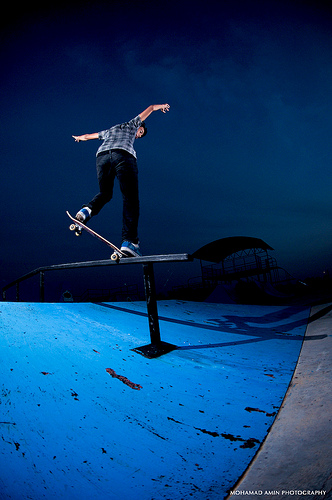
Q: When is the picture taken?
A: Nighttime.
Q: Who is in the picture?
A: A skateboarder.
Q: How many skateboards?
A: One.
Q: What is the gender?
A: Male.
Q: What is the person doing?
A: Skateboarding.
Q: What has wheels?
A: The skateboard.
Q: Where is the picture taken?
A: Skatepark.